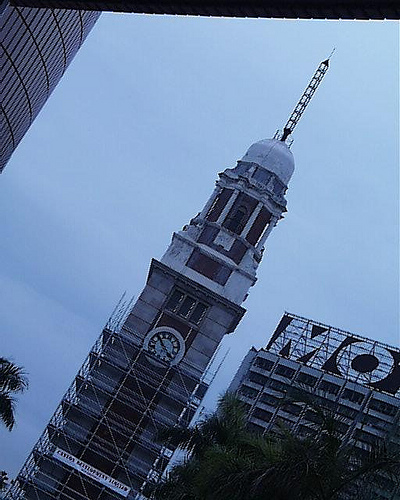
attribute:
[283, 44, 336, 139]
tip — long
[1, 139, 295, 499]
building — tall, round, partial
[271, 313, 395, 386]
letters — mo, white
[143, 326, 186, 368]
clock — old, large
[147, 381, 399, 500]
tree — palm, green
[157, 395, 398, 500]
leaves — pointed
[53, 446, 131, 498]
banner — white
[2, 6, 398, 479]
sky — blue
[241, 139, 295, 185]
dome — grey, white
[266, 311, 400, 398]
billboard — white, black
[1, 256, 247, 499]
clocktower — large